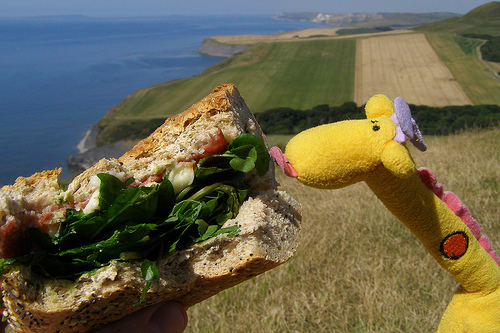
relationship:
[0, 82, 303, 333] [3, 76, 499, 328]
bread in forefront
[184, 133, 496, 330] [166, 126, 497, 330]
grass covering ground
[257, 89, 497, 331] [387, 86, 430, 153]
giraffe wearing hat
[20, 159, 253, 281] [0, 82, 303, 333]
lettuce on bread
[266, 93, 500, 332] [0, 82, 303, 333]
giraffe pretending to eat bread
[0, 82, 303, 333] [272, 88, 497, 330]
bread next to toy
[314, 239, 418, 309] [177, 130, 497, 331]
light grass on field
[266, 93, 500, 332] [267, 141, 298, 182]
giraffe has tongue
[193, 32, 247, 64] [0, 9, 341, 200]
ledge next to water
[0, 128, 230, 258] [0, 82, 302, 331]
meat between bread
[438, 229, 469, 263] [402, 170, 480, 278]
red circle on neck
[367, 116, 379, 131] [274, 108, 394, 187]
eyes on face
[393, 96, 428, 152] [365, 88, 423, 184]
hat on head